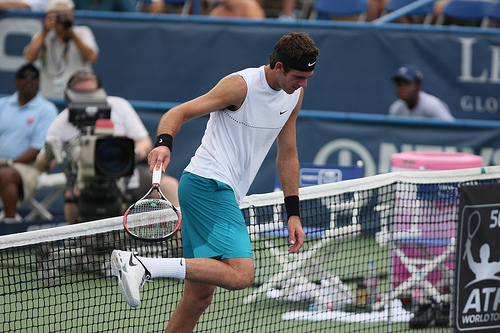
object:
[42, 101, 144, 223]
camera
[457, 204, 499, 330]
sign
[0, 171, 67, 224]
chair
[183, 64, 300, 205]
tshirt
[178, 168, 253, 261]
shorts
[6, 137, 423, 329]
court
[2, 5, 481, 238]
stands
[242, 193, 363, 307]
chair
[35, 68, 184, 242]
man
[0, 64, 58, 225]
man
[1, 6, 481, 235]
barriers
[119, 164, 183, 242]
racket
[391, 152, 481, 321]
bucket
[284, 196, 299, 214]
wrist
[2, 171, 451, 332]
net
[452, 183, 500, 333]
flag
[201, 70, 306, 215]
white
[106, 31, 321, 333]
man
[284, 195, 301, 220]
band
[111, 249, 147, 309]
shoe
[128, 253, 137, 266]
check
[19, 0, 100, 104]
man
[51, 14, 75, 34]
camera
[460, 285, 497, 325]
lettering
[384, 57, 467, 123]
man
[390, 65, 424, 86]
cap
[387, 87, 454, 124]
white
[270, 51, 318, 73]
band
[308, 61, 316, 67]
check